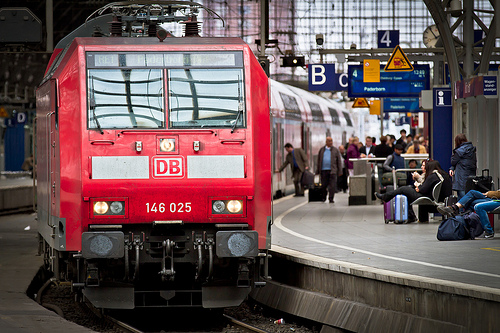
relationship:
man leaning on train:
[276, 142, 311, 197] [34, 0, 354, 310]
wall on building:
[0, 0, 32, 175] [3, 2, 498, 204]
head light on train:
[92, 201, 124, 215] [27, 32, 368, 308]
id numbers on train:
[146, 199, 193, 215] [24, 38, 290, 278]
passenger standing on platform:
[317, 135, 343, 202] [283, 149, 492, 286]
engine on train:
[31, 0, 271, 309] [34, 0, 354, 310]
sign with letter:
[426, 73, 458, 113] [429, 87, 449, 107]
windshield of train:
[87, 67, 246, 129] [27, 25, 273, 317]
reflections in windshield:
[79, 60, 246, 127] [82, 62, 256, 141]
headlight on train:
[212, 198, 244, 213] [38, 31, 346, 322]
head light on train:
[92, 201, 124, 215] [38, 31, 346, 322]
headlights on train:
[207, 193, 247, 213] [33, 0, 395, 315]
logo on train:
[151, 155, 183, 176] [34, 0, 354, 310]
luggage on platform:
[301, 162, 498, 243] [266, 153, 497, 330]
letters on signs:
[309, 63, 419, 99] [382, 47, 410, 70]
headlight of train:
[212, 198, 244, 213] [38, 31, 346, 322]